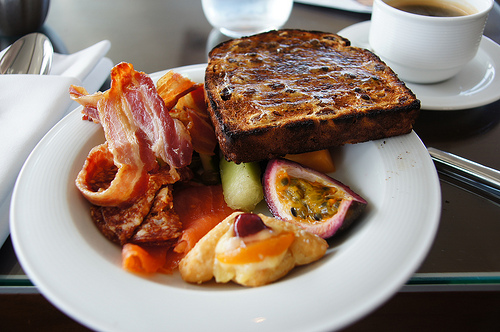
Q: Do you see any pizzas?
A: No, there are no pizzas.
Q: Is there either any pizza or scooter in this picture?
A: No, there are no pizzas or scooters.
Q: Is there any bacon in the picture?
A: Yes, there is bacon.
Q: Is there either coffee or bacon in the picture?
A: Yes, there is bacon.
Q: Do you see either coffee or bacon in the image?
A: Yes, there is bacon.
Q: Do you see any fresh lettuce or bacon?
A: Yes, there is fresh bacon.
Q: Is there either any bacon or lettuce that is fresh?
A: Yes, the bacon is fresh.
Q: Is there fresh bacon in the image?
A: Yes, there is fresh bacon.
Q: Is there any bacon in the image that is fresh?
A: Yes, there is bacon that is fresh.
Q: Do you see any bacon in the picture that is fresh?
A: Yes, there is bacon that is fresh.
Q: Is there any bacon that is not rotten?
A: Yes, there is fresh bacon.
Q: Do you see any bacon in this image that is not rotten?
A: Yes, there is fresh bacon.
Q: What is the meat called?
A: The meat is bacon.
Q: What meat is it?
A: The meat is bacon.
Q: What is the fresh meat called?
A: The meat is bacon.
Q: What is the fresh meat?
A: The meat is bacon.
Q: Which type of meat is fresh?
A: The meat is bacon.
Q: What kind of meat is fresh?
A: The meat is bacon.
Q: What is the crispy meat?
A: The meat is bacon.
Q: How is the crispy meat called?
A: The meat is bacon.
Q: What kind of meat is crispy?
A: The meat is bacon.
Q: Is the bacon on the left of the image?
A: Yes, the bacon is on the left of the image.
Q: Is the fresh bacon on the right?
A: No, the bacon is on the left of the image.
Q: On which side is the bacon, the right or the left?
A: The bacon is on the left of the image.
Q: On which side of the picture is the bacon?
A: The bacon is on the left of the image.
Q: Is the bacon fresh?
A: Yes, the bacon is fresh.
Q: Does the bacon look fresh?
A: Yes, the bacon is fresh.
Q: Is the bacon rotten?
A: No, the bacon is fresh.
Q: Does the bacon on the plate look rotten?
A: No, the bacon is fresh.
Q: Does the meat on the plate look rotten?
A: No, the bacon is fresh.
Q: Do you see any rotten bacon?
A: No, there is bacon but it is fresh.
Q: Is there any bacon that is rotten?
A: No, there is bacon but it is fresh.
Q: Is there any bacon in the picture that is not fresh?
A: No, there is bacon but it is fresh.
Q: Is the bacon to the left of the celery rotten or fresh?
A: The bacon is fresh.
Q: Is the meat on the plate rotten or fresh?
A: The bacon is fresh.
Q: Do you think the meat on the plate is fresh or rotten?
A: The bacon is fresh.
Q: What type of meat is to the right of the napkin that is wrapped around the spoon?
A: The meat is bacon.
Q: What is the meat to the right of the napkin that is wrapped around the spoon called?
A: The meat is bacon.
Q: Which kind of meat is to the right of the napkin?
A: The meat is bacon.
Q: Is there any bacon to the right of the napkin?
A: Yes, there is bacon to the right of the napkin.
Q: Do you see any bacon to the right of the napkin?
A: Yes, there is bacon to the right of the napkin.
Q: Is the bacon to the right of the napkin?
A: Yes, the bacon is to the right of the napkin.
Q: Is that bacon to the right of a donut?
A: No, the bacon is to the right of the napkin.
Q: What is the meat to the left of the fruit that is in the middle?
A: The meat is bacon.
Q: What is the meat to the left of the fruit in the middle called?
A: The meat is bacon.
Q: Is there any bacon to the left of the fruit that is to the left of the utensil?
A: Yes, there is bacon to the left of the fruit.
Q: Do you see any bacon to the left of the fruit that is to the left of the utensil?
A: Yes, there is bacon to the left of the fruit.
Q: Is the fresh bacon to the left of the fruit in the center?
A: Yes, the bacon is to the left of the fruit.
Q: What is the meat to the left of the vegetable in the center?
A: The meat is bacon.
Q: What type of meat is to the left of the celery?
A: The meat is bacon.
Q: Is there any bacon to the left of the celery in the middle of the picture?
A: Yes, there is bacon to the left of the celery.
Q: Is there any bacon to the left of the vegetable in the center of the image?
A: Yes, there is bacon to the left of the celery.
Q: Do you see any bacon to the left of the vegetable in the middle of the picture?
A: Yes, there is bacon to the left of the celery.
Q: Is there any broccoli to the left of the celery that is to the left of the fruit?
A: No, there is bacon to the left of the celery.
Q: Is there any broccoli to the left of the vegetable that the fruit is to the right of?
A: No, there is bacon to the left of the celery.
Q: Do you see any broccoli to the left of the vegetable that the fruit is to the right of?
A: No, there is bacon to the left of the celery.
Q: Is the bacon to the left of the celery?
A: Yes, the bacon is to the left of the celery.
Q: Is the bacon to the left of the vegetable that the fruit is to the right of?
A: Yes, the bacon is to the left of the celery.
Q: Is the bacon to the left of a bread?
A: No, the bacon is to the left of the celery.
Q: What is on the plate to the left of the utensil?
A: The bacon is on the plate.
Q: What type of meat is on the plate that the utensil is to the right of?
A: The meat is bacon.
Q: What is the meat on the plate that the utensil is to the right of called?
A: The meat is bacon.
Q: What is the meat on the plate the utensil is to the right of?
A: The meat is bacon.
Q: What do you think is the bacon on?
A: The bacon is on the plate.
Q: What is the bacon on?
A: The bacon is on the plate.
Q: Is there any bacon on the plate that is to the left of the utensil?
A: Yes, there is bacon on the plate.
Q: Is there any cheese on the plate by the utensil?
A: No, there is bacon on the plate.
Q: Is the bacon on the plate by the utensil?
A: Yes, the bacon is on the plate.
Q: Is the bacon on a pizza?
A: No, the bacon is on the plate.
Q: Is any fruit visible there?
A: Yes, there is a fruit.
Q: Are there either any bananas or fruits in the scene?
A: Yes, there is a fruit.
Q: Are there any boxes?
A: No, there are no boxes.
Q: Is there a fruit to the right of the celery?
A: Yes, there is a fruit to the right of the celery.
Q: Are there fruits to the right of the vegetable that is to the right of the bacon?
A: Yes, there is a fruit to the right of the celery.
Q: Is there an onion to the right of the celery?
A: No, there is a fruit to the right of the celery.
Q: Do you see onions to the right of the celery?
A: No, there is a fruit to the right of the celery.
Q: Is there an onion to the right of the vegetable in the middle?
A: No, there is a fruit to the right of the celery.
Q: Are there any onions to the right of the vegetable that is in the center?
A: No, there is a fruit to the right of the celery.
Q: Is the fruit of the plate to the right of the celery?
A: Yes, the fruit is to the right of the celery.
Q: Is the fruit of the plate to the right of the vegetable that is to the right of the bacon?
A: Yes, the fruit is to the right of the celery.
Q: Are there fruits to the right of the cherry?
A: Yes, there is a fruit to the right of the cherry.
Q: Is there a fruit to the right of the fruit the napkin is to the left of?
A: Yes, there is a fruit to the right of the cherry.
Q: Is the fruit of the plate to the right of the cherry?
A: Yes, the fruit is to the right of the cherry.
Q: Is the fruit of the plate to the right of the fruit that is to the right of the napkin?
A: Yes, the fruit is to the right of the cherry.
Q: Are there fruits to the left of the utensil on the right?
A: Yes, there is a fruit to the left of the utensil.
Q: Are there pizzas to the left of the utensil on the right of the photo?
A: No, there is a fruit to the left of the utensil.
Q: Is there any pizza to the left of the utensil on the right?
A: No, there is a fruit to the left of the utensil.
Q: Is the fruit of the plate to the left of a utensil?
A: Yes, the fruit is to the left of a utensil.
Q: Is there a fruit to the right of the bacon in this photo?
A: Yes, there is a fruit to the right of the bacon.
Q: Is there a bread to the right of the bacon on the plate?
A: No, there is a fruit to the right of the bacon.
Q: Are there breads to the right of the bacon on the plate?
A: No, there is a fruit to the right of the bacon.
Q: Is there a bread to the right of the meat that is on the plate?
A: No, there is a fruit to the right of the bacon.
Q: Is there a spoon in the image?
A: Yes, there is a spoon.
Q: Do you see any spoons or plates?
A: Yes, there is a spoon.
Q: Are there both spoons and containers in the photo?
A: No, there is a spoon but no containers.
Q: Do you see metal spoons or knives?
A: Yes, there is a metal spoon.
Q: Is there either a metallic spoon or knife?
A: Yes, there is a metal spoon.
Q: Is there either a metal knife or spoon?
A: Yes, there is a metal spoon.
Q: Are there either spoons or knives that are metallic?
A: Yes, the spoon is metallic.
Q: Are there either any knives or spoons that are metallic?
A: Yes, the spoon is metallic.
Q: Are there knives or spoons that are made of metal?
A: Yes, the spoon is made of metal.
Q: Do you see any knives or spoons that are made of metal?
A: Yes, the spoon is made of metal.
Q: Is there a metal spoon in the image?
A: Yes, there is a metal spoon.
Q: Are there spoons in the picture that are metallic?
A: Yes, there is a spoon that is metallic.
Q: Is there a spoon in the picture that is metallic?
A: Yes, there is a spoon that is metallic.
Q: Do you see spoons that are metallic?
A: Yes, there is a spoon that is metallic.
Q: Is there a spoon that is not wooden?
A: Yes, there is a metallic spoon.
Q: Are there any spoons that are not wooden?
A: Yes, there is a metallic spoon.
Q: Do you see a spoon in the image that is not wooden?
A: Yes, there is a metallic spoon.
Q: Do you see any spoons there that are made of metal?
A: Yes, there is a spoon that is made of metal.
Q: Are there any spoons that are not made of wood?
A: Yes, there is a spoon that is made of metal.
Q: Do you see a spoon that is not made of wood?
A: Yes, there is a spoon that is made of metal.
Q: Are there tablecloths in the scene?
A: No, there are no tablecloths.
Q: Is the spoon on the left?
A: Yes, the spoon is on the left of the image.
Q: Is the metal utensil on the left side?
A: Yes, the spoon is on the left of the image.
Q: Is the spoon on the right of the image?
A: No, the spoon is on the left of the image.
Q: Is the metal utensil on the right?
A: No, the spoon is on the left of the image.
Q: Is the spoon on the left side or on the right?
A: The spoon is on the left of the image.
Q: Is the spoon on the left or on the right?
A: The spoon is on the left of the image.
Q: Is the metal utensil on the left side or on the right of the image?
A: The spoon is on the left of the image.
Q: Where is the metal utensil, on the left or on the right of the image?
A: The spoon is on the left of the image.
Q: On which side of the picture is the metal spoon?
A: The spoon is on the left of the image.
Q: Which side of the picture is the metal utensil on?
A: The spoon is on the left of the image.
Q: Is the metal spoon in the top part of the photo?
A: Yes, the spoon is in the top of the image.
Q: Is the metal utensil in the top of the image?
A: Yes, the spoon is in the top of the image.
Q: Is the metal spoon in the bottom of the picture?
A: No, the spoon is in the top of the image.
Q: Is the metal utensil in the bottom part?
A: No, the spoon is in the top of the image.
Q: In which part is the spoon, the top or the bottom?
A: The spoon is in the top of the image.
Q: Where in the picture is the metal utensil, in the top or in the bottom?
A: The spoon is in the top of the image.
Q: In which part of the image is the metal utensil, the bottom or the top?
A: The spoon is in the top of the image.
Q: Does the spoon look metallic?
A: Yes, the spoon is metallic.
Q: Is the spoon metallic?
A: Yes, the spoon is metallic.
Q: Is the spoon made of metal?
A: Yes, the spoon is made of metal.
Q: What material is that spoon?
A: The spoon is made of metal.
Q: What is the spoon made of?
A: The spoon is made of metal.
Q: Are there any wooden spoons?
A: No, there is a spoon but it is metallic.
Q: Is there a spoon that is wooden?
A: No, there is a spoon but it is metallic.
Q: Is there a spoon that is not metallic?
A: No, there is a spoon but it is metallic.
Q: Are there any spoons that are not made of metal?
A: No, there is a spoon but it is made of metal.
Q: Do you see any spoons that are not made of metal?
A: No, there is a spoon but it is made of metal.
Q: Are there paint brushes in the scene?
A: No, there are no paint brushes.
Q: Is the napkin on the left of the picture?
A: Yes, the napkin is on the left of the image.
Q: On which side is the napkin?
A: The napkin is on the left of the image.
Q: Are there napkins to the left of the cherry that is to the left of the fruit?
A: Yes, there is a napkin to the left of the cherry.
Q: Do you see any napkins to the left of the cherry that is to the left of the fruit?
A: Yes, there is a napkin to the left of the cherry.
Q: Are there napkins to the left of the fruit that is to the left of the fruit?
A: Yes, there is a napkin to the left of the cherry.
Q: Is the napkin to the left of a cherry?
A: Yes, the napkin is to the left of a cherry.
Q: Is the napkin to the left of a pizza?
A: No, the napkin is to the left of a cherry.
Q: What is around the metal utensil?
A: The napkin is around the spoon.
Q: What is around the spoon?
A: The napkin is around the spoon.